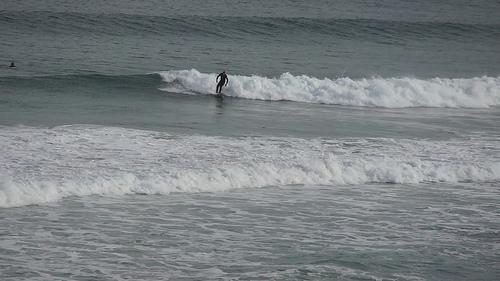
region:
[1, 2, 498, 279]
the photo is in black & white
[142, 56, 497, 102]
the foam on the waves is white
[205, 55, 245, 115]
the man is surfing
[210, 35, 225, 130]
the man is wearing a wetsuit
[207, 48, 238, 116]
the man's board appears to be white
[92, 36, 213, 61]
the water is grey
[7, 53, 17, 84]
a man is in the water in the background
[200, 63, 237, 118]
the man is wearing a wet suit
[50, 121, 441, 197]
the waves do not appear to be very large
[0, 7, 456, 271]
the whole scene looks cold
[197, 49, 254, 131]
a person on the wave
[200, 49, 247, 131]
appears to be a surfer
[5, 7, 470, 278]
a scene outside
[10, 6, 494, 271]
a scene at the beach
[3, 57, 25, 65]
either a bird or person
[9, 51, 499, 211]
two large waves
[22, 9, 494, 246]
a scene occurring during the day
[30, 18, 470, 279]
a clear water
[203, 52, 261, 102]
a surfer standing on wave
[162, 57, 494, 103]
a white wave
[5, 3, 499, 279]
The water is rough.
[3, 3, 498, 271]
The water is engaging.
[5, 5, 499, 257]
The water is splashing.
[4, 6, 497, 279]
The water is choppy.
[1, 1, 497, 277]
The water is intense.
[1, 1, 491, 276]
The water is zealous.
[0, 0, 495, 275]
The water is aggressive.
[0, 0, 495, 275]
The water is assertive.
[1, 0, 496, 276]
The water is rambunctious.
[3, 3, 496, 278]
The water is lively.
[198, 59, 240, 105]
A surfer riding a wave.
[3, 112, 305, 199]
A white wave moving toward the beach.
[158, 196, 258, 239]
Foam from the water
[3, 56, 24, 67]
A head bobbing in the water.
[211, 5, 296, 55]
The water is a light blue color.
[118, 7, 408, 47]
A wave heading toward shore.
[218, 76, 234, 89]
The man is wearing a dark body suit.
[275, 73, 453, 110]
The surf water is bright white.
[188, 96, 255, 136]
The water is calm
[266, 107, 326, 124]
reflection from the sky appearing on water's surface.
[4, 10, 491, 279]
The water is foamy.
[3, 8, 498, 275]
The water is frothy.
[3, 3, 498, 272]
The water is fervent.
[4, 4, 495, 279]
The water is rugged.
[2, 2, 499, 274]
The water is turbulent.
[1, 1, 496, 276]
The water is powerful.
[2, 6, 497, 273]
The water is persistent.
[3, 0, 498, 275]
The water is pushy.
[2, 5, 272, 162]
Two people in water.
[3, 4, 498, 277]
The water is ardent.